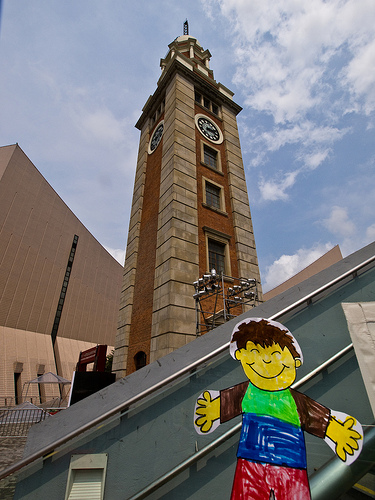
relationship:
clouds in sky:
[0, 0, 375, 296] [0, 0, 374, 296]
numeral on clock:
[198, 121, 202, 124] [192, 111, 224, 143]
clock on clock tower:
[141, 116, 170, 155] [111, 18, 263, 382]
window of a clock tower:
[202, 143, 217, 170] [111, 19, 263, 380]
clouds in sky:
[242, 9, 349, 163] [271, 192, 303, 252]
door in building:
[197, 174, 230, 219] [133, 22, 258, 307]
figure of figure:
[191, 318, 363, 500] [191, 318, 363, 500]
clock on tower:
[186, 102, 224, 144] [111, 17, 265, 367]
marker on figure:
[264, 437, 287, 464] [191, 318, 363, 500]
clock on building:
[194, 113, 223, 145] [5, 111, 140, 377]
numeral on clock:
[198, 121, 202, 125] [131, 118, 181, 158]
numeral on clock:
[211, 125, 214, 130] [192, 111, 224, 143]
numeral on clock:
[207, 131, 213, 139] [196, 109, 224, 144]